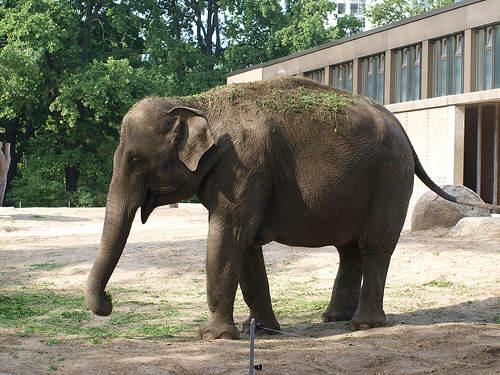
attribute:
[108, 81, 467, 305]
elephant — brown, large, huge, still, close, here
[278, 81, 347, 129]
grass — standing, green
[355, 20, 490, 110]
building — behind, brown, tan, here, large, white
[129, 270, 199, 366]
dirt — green, brown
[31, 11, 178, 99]
trees — bushy, close, green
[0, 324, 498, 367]
mound — rounded 